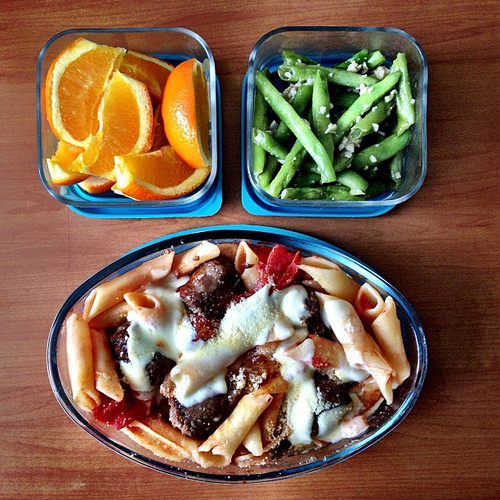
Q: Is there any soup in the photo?
A: No, there is no soup.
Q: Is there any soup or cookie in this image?
A: No, there are no soup or cookies.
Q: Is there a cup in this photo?
A: No, there are no cups.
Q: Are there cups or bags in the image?
A: No, there are no cups or bags.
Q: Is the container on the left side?
A: Yes, the container is on the left of the image.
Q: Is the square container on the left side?
A: Yes, the container is on the left of the image.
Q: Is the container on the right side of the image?
A: No, the container is on the left of the image.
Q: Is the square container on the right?
A: No, the container is on the left of the image.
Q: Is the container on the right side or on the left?
A: The container is on the left of the image.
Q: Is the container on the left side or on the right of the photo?
A: The container is on the left of the image.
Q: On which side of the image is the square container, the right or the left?
A: The container is on the left of the image.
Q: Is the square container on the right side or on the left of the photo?
A: The container is on the left of the image.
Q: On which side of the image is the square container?
A: The container is on the left of the image.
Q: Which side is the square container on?
A: The container is on the left of the image.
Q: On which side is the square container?
A: The container is on the left of the image.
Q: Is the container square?
A: Yes, the container is square.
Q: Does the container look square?
A: Yes, the container is square.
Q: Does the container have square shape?
A: Yes, the container is square.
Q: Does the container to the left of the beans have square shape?
A: Yes, the container is square.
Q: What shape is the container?
A: The container is square.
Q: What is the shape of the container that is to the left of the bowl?
A: The container is square.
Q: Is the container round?
A: No, the container is square.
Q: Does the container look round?
A: No, the container is square.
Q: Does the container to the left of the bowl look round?
A: No, the container is square.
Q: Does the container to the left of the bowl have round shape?
A: No, the container is square.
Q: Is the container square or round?
A: The container is square.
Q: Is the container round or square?
A: The container is square.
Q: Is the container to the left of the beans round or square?
A: The container is square.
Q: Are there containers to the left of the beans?
A: Yes, there is a container to the left of the beans.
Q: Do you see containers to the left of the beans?
A: Yes, there is a container to the left of the beans.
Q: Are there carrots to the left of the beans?
A: No, there is a container to the left of the beans.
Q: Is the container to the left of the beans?
A: Yes, the container is to the left of the beans.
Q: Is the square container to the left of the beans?
A: Yes, the container is to the left of the beans.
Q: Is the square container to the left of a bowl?
A: Yes, the container is to the left of a bowl.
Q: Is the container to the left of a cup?
A: No, the container is to the left of a bowl.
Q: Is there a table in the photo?
A: Yes, there is a table.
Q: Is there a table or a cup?
A: Yes, there is a table.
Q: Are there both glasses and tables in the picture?
A: No, there is a table but no glasses.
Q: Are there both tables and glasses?
A: No, there is a table but no glasses.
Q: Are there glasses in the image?
A: No, there are no glasses.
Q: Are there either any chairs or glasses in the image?
A: No, there are no glasses or chairs.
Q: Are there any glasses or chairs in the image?
A: No, there are no glasses or chairs.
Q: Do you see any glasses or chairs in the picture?
A: No, there are no glasses or chairs.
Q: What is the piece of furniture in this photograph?
A: The piece of furniture is a table.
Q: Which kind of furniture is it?
A: The piece of furniture is a table.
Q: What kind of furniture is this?
A: That is a table.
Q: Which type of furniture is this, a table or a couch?
A: That is a table.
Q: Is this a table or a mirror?
A: This is a table.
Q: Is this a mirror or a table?
A: This is a table.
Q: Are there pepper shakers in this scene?
A: No, there are no pepper shakers.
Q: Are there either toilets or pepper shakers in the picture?
A: No, there are no pepper shakers or toilets.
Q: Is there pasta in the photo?
A: Yes, there is pasta.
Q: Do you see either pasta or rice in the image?
A: Yes, there is pasta.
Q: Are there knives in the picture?
A: No, there are no knives.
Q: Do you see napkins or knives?
A: No, there are no knives or napkins.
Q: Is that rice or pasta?
A: That is pasta.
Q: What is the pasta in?
A: The pasta is in the bowl.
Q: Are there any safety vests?
A: No, there are no safety vests.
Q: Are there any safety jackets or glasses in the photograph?
A: No, there are no safety jackets or glasses.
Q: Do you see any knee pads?
A: No, there are no knee pads.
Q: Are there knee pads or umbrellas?
A: No, there are no knee pads or umbrellas.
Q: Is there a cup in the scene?
A: No, there are no cups.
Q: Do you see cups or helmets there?
A: No, there are no cups or helmets.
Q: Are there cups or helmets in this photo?
A: No, there are no cups or helmets.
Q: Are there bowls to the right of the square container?
A: Yes, there is a bowl to the right of the container.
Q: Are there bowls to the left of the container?
A: No, the bowl is to the right of the container.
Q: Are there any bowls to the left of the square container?
A: No, the bowl is to the right of the container.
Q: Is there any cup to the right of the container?
A: No, there is a bowl to the right of the container.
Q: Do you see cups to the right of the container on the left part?
A: No, there is a bowl to the right of the container.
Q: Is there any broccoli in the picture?
A: No, there is no broccoli.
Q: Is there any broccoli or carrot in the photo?
A: No, there are no broccoli or carrots.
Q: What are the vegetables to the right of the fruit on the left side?
A: The vegetables are beans.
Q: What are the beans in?
A: The beans are in the bowl.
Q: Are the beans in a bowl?
A: Yes, the beans are in a bowl.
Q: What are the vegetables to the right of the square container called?
A: The vegetables are beans.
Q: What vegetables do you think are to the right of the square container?
A: The vegetables are beans.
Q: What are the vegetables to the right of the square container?
A: The vegetables are beans.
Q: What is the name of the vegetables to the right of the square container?
A: The vegetables are beans.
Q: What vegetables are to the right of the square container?
A: The vegetables are beans.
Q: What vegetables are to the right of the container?
A: The vegetables are beans.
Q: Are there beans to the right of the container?
A: Yes, there are beans to the right of the container.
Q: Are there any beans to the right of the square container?
A: Yes, there are beans to the right of the container.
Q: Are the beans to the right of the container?
A: Yes, the beans are to the right of the container.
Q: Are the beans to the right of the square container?
A: Yes, the beans are to the right of the container.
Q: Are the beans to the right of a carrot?
A: No, the beans are to the right of the container.